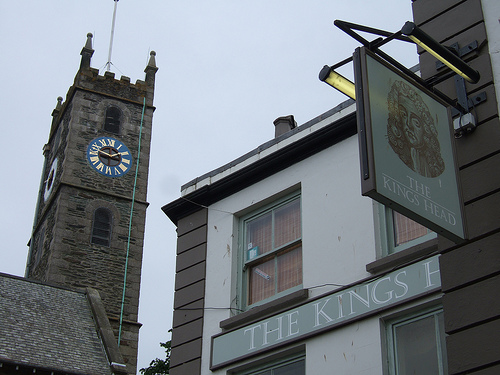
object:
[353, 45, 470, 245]
big sign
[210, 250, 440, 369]
banner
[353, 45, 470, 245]
sign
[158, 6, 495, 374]
building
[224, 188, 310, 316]
window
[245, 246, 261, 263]
label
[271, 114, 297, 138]
chimney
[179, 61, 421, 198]
gray edge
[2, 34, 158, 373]
building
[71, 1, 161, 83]
spirals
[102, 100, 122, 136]
window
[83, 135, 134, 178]
clock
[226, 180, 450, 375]
windows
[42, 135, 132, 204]
clocks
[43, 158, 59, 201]
clock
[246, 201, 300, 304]
blinds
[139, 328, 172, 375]
leaves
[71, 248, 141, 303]
bricks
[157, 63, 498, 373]
wall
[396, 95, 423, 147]
face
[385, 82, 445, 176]
man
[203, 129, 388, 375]
white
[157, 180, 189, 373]
edge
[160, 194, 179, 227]
tip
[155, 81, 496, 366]
part of the wall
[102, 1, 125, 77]
pole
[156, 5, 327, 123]
sky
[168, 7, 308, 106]
blue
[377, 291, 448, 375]
window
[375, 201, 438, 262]
window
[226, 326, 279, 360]
part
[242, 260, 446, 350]
words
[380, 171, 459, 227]
words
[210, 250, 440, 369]
sign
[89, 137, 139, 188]
roman numerals